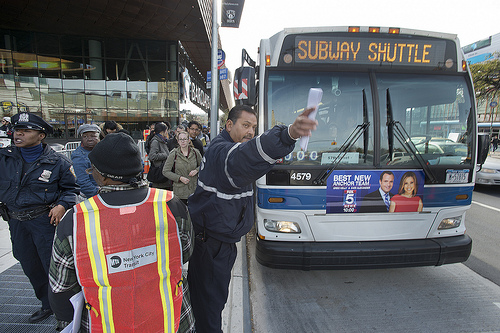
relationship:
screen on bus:
[289, 35, 442, 70] [253, 23, 490, 265]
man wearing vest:
[47, 132, 195, 332] [57, 170, 224, 316]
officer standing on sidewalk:
[0, 114, 77, 332] [0, 184, 232, 331]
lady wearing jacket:
[161, 132, 203, 206] [165, 147, 197, 195]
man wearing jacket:
[184, 104, 317, 333] [182, 124, 301, 239]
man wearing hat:
[47, 132, 195, 332] [87, 125, 150, 180]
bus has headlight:
[253, 23, 490, 265] [262, 218, 301, 233]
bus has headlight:
[253, 23, 490, 265] [437, 215, 460, 232]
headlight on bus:
[262, 218, 301, 233] [233, 25, 490, 270]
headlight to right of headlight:
[262, 218, 301, 233] [437, 215, 462, 228]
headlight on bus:
[431, 209, 466, 244] [253, 23, 490, 265]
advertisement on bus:
[314, 165, 421, 216] [253, 23, 490, 265]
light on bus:
[264, 195, 284, 205] [233, 25, 490, 270]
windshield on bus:
[263, 67, 476, 185] [238, 16, 494, 266]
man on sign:
[356, 170, 396, 213] [327, 164, 432, 213]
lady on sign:
[387, 172, 427, 211] [327, 164, 432, 213]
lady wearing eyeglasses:
[163, 128, 208, 224] [176, 134, 188, 143]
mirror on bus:
[473, 132, 490, 172] [253, 23, 490, 265]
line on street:
[470, 199, 499, 218] [260, 186, 499, 331]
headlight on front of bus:
[262, 218, 301, 233] [206, 55, 475, 255]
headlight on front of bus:
[437, 215, 460, 232] [206, 55, 475, 255]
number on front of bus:
[289, 171, 311, 181] [233, 25, 490, 270]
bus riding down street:
[233, 25, 490, 270] [260, 186, 499, 331]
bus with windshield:
[233, 25, 490, 270] [264, 69, 459, 179]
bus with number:
[233, 25, 490, 270] [289, 171, 311, 181]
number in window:
[289, 171, 311, 181] [273, 73, 465, 198]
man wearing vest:
[84, 147, 176, 214] [71, 205, 195, 332]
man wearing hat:
[47, 132, 195, 332] [92, 131, 152, 178]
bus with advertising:
[233, 25, 490, 270] [330, 167, 437, 229]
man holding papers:
[157, 97, 299, 302] [276, 76, 328, 161]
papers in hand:
[276, 76, 328, 161] [283, 107, 333, 143]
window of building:
[138, 44, 198, 86] [26, 6, 226, 204]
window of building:
[145, 59, 180, 83] [2, 1, 234, 142]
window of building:
[104, 41, 131, 61] [7, 36, 208, 166]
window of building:
[10, 56, 194, 134] [2, 1, 234, 142]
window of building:
[57, 34, 85, 58] [2, 1, 234, 142]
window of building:
[3, 75, 177, 127] [1, 3, 228, 133]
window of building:
[3, 75, 177, 127] [0, 0, 237, 155]